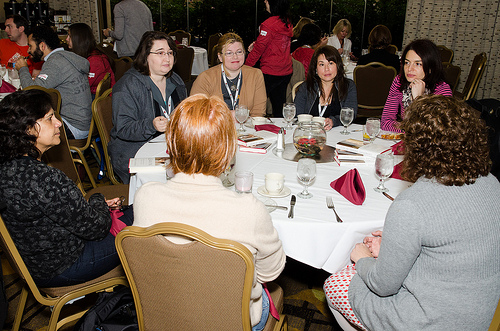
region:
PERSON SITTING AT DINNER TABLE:
[10, 85, 116, 275]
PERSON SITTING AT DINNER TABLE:
[388, 38, 447, 99]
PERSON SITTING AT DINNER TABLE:
[313, 34, 347, 118]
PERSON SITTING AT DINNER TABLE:
[217, 25, 261, 115]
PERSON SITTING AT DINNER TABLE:
[1, 11, 30, 84]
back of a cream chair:
[102, 220, 252, 327]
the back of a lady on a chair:
[108, 88, 292, 329]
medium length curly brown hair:
[395, 96, 491, 193]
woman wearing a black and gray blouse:
[5, 72, 112, 267]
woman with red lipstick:
[189, 29, 263, 73]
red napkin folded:
[330, 169, 370, 206]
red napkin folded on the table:
[326, 164, 371, 206]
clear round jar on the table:
[283, 114, 347, 174]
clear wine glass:
[296, 154, 320, 204]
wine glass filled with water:
[367, 150, 395, 195]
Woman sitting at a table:
[365, 18, 395, 82]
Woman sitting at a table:
[328, 16, 368, 93]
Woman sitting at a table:
[301, 38, 353, 123]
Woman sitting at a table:
[381, 62, 472, 326]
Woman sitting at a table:
[145, 88, 274, 258]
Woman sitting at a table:
[117, 19, 208, 155]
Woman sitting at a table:
[8, 70, 128, 284]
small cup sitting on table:
[339, 104, 354, 139]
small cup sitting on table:
[280, 93, 300, 132]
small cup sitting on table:
[235, 101, 250, 139]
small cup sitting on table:
[229, 166, 258, 207]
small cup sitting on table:
[290, 151, 316, 211]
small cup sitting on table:
[374, 145, 395, 205]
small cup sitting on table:
[308, 109, 333, 128]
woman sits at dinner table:
[128, 91, 284, 327]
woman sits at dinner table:
[322, 92, 499, 328]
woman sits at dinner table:
[380, 41, 455, 131]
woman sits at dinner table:
[292, 45, 358, 127]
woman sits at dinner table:
[190, 32, 266, 121]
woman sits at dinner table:
[113, 28, 185, 168]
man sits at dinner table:
[8, 21, 93, 151]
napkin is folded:
[329, 168, 369, 208]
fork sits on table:
[322, 192, 343, 224]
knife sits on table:
[285, 192, 297, 219]